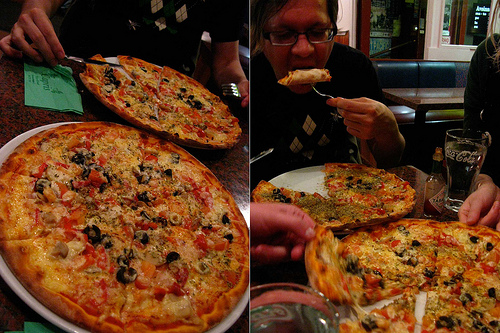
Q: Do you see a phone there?
A: Yes, there is a phone.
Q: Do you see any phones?
A: Yes, there is a phone.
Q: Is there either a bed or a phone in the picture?
A: Yes, there is a phone.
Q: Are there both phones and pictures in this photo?
A: No, there is a phone but no pictures.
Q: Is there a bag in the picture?
A: No, there are no bags.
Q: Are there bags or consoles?
A: No, there are no bags or consoles.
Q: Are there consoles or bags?
A: No, there are no bags or consoles.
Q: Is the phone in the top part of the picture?
A: Yes, the phone is in the top of the image.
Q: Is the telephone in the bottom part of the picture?
A: No, the telephone is in the top of the image.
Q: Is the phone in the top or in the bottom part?
A: The phone is in the top of the image.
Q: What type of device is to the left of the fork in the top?
A: The device is a phone.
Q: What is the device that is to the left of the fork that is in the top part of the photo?
A: The device is a phone.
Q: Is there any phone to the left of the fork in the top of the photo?
A: Yes, there is a phone to the left of the fork.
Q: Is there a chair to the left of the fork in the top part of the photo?
A: No, there is a phone to the left of the fork.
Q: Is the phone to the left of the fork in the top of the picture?
A: Yes, the phone is to the left of the fork.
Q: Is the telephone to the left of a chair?
A: No, the telephone is to the left of the fork.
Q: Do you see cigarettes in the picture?
A: No, there are no cigarettes.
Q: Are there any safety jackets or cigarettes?
A: No, there are no cigarettes or safety jackets.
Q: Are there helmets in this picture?
A: No, there are no helmets.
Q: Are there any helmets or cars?
A: No, there are no helmets or cars.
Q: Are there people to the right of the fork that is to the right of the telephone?
A: Yes, there is a person to the right of the fork.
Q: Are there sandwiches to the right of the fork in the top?
A: No, there is a person to the right of the fork.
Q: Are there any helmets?
A: No, there are no helmets.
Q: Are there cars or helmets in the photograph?
A: No, there are no helmets or cars.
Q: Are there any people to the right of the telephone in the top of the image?
A: Yes, there is a person to the right of the phone.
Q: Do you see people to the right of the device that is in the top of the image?
A: Yes, there is a person to the right of the phone.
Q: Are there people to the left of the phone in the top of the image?
A: No, the person is to the right of the phone.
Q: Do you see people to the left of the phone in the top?
A: No, the person is to the right of the phone.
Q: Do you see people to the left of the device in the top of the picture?
A: No, the person is to the right of the phone.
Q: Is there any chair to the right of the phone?
A: No, there is a person to the right of the phone.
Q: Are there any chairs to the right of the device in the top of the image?
A: No, there is a person to the right of the phone.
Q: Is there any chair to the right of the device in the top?
A: No, there is a person to the right of the phone.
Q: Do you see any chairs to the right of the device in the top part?
A: No, there is a person to the right of the phone.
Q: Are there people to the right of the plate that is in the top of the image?
A: Yes, there is a person to the right of the plate.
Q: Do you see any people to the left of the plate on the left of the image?
A: No, the person is to the right of the plate.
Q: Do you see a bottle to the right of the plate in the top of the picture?
A: No, there is a person to the right of the plate.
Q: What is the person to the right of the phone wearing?
A: The person is wearing a shirt.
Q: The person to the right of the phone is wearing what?
A: The person is wearing a shirt.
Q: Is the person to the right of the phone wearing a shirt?
A: Yes, the person is wearing a shirt.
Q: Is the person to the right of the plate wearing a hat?
A: No, the person is wearing a shirt.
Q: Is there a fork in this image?
A: Yes, there is a fork.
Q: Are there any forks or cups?
A: Yes, there is a fork.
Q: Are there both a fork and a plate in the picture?
A: Yes, there are both a fork and a plate.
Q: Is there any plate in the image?
A: Yes, there is a plate.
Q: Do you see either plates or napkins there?
A: Yes, there is a plate.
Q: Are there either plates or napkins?
A: Yes, there is a plate.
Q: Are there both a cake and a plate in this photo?
A: No, there is a plate but no cakes.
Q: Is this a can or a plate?
A: This is a plate.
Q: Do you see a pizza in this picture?
A: Yes, there is a pizza.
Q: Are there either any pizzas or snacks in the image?
A: Yes, there is a pizza.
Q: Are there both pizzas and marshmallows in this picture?
A: No, there is a pizza but no marshmallows.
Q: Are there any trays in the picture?
A: No, there are no trays.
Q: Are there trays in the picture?
A: No, there are no trays.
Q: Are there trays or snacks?
A: No, there are no trays or snacks.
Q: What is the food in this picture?
A: The food is a pizza.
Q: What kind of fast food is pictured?
A: The fast food is a pizza.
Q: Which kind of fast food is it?
A: The food is a pizza.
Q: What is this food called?
A: That is a pizza.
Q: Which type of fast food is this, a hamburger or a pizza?
A: That is a pizza.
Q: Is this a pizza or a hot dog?
A: This is a pizza.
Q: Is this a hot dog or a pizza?
A: This is a pizza.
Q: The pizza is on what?
A: The pizza is on the plate.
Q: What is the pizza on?
A: The pizza is on the plate.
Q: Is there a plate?
A: Yes, there is a plate.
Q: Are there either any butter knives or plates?
A: Yes, there is a plate.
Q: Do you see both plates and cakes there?
A: No, there is a plate but no cakes.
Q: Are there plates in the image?
A: Yes, there is a plate.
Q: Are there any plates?
A: Yes, there is a plate.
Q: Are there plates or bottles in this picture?
A: Yes, there is a plate.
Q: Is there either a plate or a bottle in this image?
A: Yes, there is a plate.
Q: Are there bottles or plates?
A: Yes, there is a plate.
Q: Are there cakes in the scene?
A: No, there are no cakes.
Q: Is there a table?
A: Yes, there is a table.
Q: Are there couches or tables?
A: Yes, there is a table.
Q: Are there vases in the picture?
A: No, there are no vases.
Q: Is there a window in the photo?
A: Yes, there is a window.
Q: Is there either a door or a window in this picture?
A: Yes, there is a window.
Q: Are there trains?
A: No, there are no trains.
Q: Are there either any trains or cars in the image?
A: No, there are no trains or cars.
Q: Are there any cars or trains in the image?
A: No, there are no trains or cars.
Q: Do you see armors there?
A: No, there are no armors.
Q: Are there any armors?
A: No, there are no armors.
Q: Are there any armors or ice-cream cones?
A: No, there are no armors or ice-cream cones.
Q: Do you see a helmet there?
A: No, there are no helmets.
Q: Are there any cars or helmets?
A: No, there are no helmets or cars.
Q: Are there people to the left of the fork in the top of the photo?
A: Yes, there is a person to the left of the fork.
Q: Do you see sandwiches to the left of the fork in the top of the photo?
A: No, there is a person to the left of the fork.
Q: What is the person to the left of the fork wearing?
A: The person is wearing a shirt.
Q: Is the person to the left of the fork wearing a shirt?
A: Yes, the person is wearing a shirt.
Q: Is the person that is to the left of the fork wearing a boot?
A: No, the person is wearing a shirt.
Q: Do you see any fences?
A: No, there are no fences.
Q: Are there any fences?
A: No, there are no fences.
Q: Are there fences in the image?
A: No, there are no fences.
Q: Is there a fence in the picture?
A: No, there are no fences.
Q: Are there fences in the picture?
A: No, there are no fences.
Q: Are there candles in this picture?
A: No, there are no candles.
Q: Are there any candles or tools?
A: No, there are no candles or tools.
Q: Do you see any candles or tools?
A: No, there are no candles or tools.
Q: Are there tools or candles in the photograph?
A: No, there are no candles or tools.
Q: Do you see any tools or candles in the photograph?
A: No, there are no candles or tools.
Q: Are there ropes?
A: No, there are no ropes.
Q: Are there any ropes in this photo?
A: No, there are no ropes.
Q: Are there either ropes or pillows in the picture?
A: No, there are no ropes or pillows.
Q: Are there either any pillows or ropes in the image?
A: No, there are no ropes or pillows.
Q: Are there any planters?
A: No, there are no planters.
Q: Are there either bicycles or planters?
A: No, there are no planters or bicycles.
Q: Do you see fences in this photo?
A: No, there are no fences.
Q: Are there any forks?
A: Yes, there is a fork.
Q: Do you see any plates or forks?
A: Yes, there is a fork.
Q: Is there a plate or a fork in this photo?
A: Yes, there is a fork.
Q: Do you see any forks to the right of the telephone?
A: Yes, there is a fork to the right of the telephone.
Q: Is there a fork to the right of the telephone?
A: Yes, there is a fork to the right of the telephone.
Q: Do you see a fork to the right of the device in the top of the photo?
A: Yes, there is a fork to the right of the telephone.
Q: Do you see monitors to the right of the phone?
A: No, there is a fork to the right of the phone.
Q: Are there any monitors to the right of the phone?
A: No, there is a fork to the right of the phone.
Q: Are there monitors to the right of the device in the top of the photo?
A: No, there is a fork to the right of the phone.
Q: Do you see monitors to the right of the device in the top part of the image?
A: No, there is a fork to the right of the phone.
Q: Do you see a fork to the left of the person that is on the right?
A: Yes, there is a fork to the left of the person.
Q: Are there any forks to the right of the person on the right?
A: No, the fork is to the left of the person.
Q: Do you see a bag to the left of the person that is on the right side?
A: No, there is a fork to the left of the person.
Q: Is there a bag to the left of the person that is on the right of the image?
A: No, there is a fork to the left of the person.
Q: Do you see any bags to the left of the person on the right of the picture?
A: No, there is a fork to the left of the person.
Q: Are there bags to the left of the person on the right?
A: No, there is a fork to the left of the person.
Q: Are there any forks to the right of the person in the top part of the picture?
A: Yes, there is a fork to the right of the person.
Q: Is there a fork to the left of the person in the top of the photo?
A: No, the fork is to the right of the person.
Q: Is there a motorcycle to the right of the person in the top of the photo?
A: No, there is a fork to the right of the person.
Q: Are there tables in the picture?
A: Yes, there is a table.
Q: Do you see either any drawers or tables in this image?
A: Yes, there is a table.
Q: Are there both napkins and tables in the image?
A: Yes, there are both a table and a napkin.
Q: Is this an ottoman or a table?
A: This is a table.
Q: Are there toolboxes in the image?
A: No, there are no toolboxes.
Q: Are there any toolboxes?
A: No, there are no toolboxes.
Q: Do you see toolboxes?
A: No, there are no toolboxes.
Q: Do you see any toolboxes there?
A: No, there are no toolboxes.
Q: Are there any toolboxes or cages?
A: No, there are no toolboxes or cages.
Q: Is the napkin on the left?
A: Yes, the napkin is on the left of the image.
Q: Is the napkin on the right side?
A: No, the napkin is on the left of the image.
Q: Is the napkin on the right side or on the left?
A: The napkin is on the left of the image.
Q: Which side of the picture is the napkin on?
A: The napkin is on the left of the image.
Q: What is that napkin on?
A: The napkin is on the table.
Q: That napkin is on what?
A: The napkin is on the table.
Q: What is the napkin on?
A: The napkin is on the table.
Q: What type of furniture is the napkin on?
A: The napkin is on the table.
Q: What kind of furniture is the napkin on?
A: The napkin is on the table.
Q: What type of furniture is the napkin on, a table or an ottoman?
A: The napkin is on a table.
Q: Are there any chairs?
A: No, there are no chairs.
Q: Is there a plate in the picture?
A: Yes, there is a plate.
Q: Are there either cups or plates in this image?
A: Yes, there is a plate.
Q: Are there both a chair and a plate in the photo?
A: No, there is a plate but no chairs.